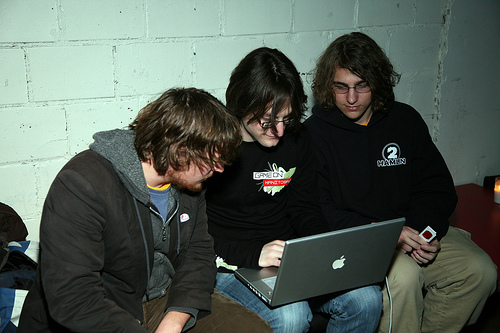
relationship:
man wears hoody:
[39, 93, 235, 332] [52, 129, 225, 332]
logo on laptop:
[324, 249, 351, 270] [234, 212, 407, 309]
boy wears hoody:
[301, 30, 496, 332] [308, 100, 457, 254]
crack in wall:
[422, 2, 452, 146] [2, 1, 498, 179]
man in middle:
[205, 48, 384, 330] [214, 37, 377, 332]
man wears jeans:
[205, 48, 384, 330] [217, 267, 383, 332]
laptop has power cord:
[234, 212, 407, 309] [375, 275, 396, 332]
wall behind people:
[2, 1, 498, 179] [62, 24, 497, 332]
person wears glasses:
[301, 30, 496, 332] [332, 81, 372, 95]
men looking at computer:
[62, 24, 497, 332] [234, 212, 407, 309]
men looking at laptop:
[62, 24, 497, 332] [234, 212, 407, 309]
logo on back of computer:
[324, 249, 351, 270] [234, 212, 407, 309]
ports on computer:
[244, 278, 269, 307] [234, 212, 407, 309]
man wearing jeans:
[205, 48, 384, 330] [217, 267, 383, 332]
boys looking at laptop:
[62, 24, 497, 332] [234, 212, 407, 309]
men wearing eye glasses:
[62, 24, 497, 332] [194, 75, 370, 168]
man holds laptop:
[205, 48, 384, 330] [234, 212, 407, 309]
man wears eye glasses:
[205, 48, 384, 330] [254, 116, 298, 131]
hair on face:
[134, 87, 243, 176] [174, 147, 225, 194]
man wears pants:
[301, 30, 496, 332] [376, 224, 498, 332]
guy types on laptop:
[205, 48, 384, 330] [234, 212, 407, 309]